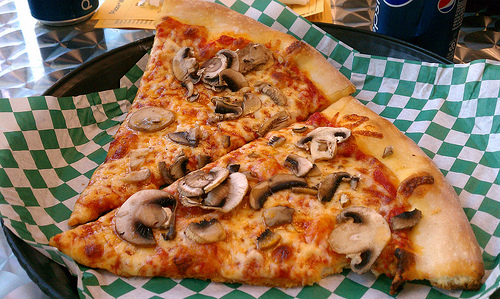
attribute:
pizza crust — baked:
[403, 183, 483, 290]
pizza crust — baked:
[308, 52, 410, 173]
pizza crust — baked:
[159, 0, 311, 42]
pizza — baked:
[28, 25, 490, 292]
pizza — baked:
[49, 1, 484, 296]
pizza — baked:
[94, 31, 332, 243]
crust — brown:
[326, 99, 483, 289]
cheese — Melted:
[228, 230, 243, 247]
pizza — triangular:
[68, 2, 358, 229]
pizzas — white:
[61, 13, 476, 287]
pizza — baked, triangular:
[42, 91, 491, 296]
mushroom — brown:
[295, 122, 349, 161]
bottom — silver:
[34, 7, 104, 27]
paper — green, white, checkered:
[3, 20, 498, 297]